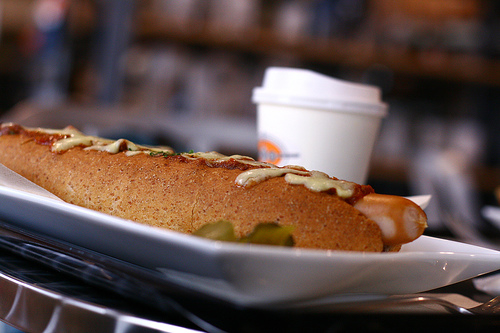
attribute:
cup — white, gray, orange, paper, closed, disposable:
[249, 61, 391, 190]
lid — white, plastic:
[249, 62, 393, 122]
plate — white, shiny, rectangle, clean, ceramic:
[1, 157, 500, 307]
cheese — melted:
[2, 117, 358, 199]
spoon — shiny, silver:
[253, 282, 499, 321]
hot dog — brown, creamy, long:
[346, 186, 434, 243]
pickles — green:
[193, 212, 299, 251]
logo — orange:
[251, 138, 287, 167]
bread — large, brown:
[0, 115, 403, 257]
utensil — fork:
[248, 252, 500, 325]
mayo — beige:
[4, 115, 359, 203]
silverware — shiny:
[152, 275, 499, 331]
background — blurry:
[1, 0, 500, 248]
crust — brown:
[0, 120, 384, 252]